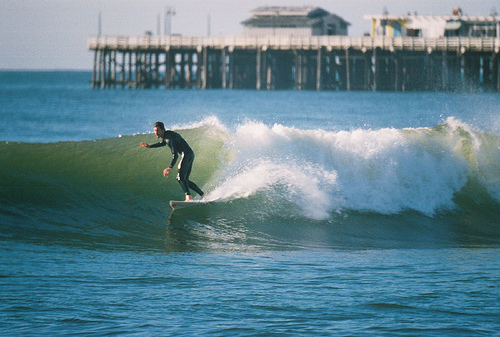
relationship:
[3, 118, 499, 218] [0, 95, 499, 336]
wave in ocean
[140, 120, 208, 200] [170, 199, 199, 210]
man atop surfboard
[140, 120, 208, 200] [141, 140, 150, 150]
man has a hand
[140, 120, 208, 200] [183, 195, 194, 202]
man has a foot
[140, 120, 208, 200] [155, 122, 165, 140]
man has a head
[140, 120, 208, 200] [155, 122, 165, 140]
man has head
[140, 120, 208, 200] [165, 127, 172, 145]
man has shoulder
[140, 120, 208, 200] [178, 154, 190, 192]
man has leg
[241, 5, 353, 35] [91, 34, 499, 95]
house atop pier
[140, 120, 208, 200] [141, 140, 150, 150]
man has hand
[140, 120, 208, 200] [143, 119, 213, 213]
man wearing wetsuit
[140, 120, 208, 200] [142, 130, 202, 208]
man wearing wetsuit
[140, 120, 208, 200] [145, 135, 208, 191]
man wearing wetsuit